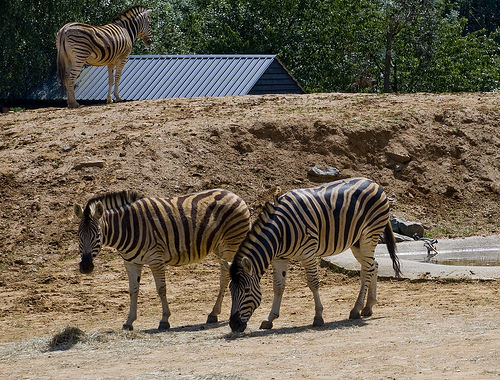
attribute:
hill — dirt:
[1, 93, 499, 313]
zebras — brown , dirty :
[51, 136, 413, 344]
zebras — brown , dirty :
[27, 1, 187, 104]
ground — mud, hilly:
[0, 90, 498, 360]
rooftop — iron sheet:
[23, 52, 305, 102]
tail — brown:
[379, 215, 407, 282]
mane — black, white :
[109, 2, 146, 22]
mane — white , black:
[78, 189, 144, 242]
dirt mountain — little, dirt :
[1, 90, 493, 320]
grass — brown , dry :
[1, 325, 152, 356]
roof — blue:
[27, 52, 307, 102]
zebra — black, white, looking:
[220, 169, 414, 328]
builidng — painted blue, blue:
[62, 37, 278, 102]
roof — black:
[87, 15, 299, 167]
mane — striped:
[85, 188, 145, 208]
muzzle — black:
[76, 234, 95, 280]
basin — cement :
[401, 238, 498, 285]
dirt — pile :
[6, 107, 474, 169]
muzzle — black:
[224, 302, 273, 348]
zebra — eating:
[244, 170, 424, 366]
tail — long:
[384, 217, 404, 281]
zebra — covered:
[270, 192, 428, 296]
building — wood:
[243, 57, 296, 100]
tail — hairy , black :
[381, 206, 407, 274]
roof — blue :
[31, 31, 311, 105]